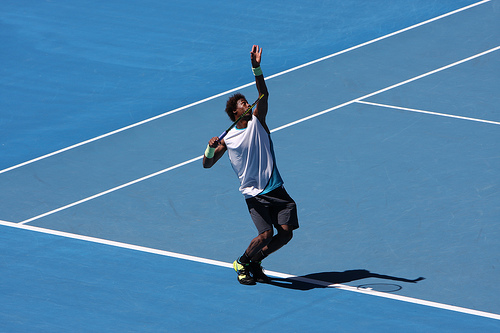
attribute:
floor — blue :
[62, 51, 175, 107]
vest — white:
[223, 112, 284, 199]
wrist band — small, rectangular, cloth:
[233, 65, 279, 87]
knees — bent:
[256, 229, 293, 244]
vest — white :
[202, 117, 299, 202]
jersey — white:
[215, 114, 284, 198]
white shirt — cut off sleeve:
[221, 112, 283, 199]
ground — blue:
[313, 34, 451, 185]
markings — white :
[3, 0, 498, 324]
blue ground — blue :
[3, 4, 498, 331]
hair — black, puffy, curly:
[217, 90, 236, 115]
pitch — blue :
[0, 4, 496, 331]